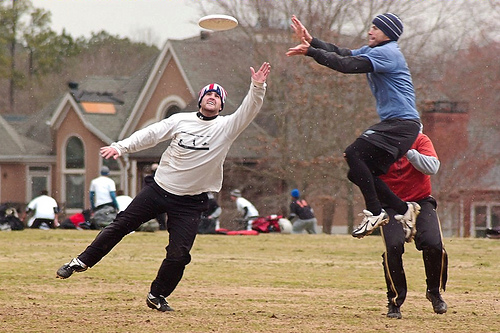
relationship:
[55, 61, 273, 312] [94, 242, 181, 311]
man wearing black pants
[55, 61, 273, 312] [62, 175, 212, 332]
man wearing black pants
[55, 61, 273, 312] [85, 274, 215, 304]
man wearing black pants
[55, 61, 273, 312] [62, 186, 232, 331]
man wearing black pants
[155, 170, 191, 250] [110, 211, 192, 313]
man wearing black pants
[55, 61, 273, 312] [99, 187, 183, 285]
man wearing black pants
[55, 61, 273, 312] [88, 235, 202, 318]
man wearing black pants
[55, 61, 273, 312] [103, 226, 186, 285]
man wearing black pants